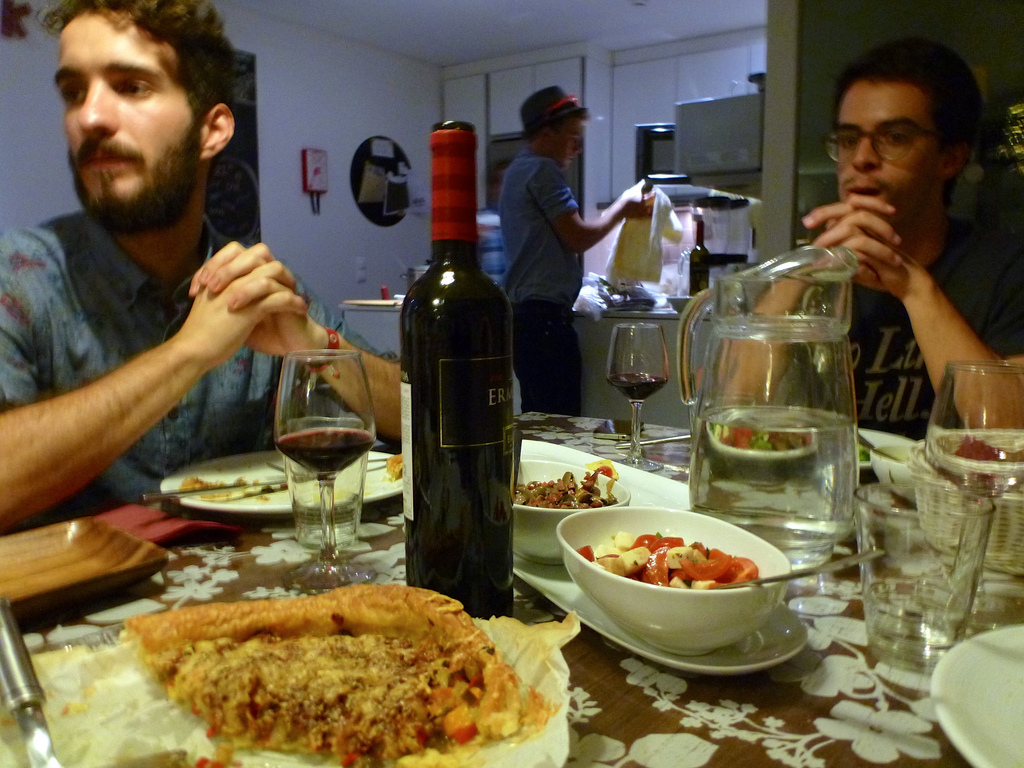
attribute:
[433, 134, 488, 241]
top — red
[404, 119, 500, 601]
bottle — wine